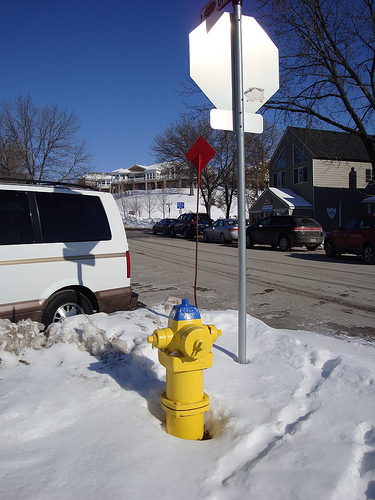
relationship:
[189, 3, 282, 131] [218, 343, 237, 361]
traffic sign has a shadow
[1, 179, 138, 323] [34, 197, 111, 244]
van has a window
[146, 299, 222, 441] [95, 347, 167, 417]
hydrant has a shadow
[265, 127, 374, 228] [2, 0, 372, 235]
building in distance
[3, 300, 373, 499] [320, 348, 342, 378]
snow has foot steps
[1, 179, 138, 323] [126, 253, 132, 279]
van has a light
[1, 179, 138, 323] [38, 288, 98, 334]
van has a tire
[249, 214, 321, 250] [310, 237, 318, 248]
car has a plate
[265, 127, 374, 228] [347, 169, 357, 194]
building has a window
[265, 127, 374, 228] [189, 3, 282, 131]
building near traffic sign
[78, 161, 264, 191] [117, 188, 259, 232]
building on a hill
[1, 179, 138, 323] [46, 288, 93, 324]
van has a tire